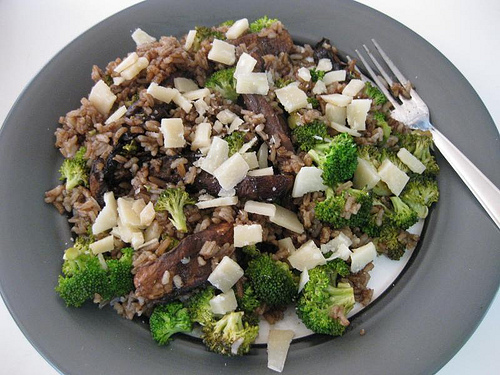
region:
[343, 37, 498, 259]
a large metal fork.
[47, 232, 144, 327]
a piece of broccoli on a plate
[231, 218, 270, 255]
a piece of food on a plate.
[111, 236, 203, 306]
a piece of meat on a plate.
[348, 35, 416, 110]
prongs on a metal fork.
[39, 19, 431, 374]
a pile of food on a plate.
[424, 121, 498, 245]
a handle on a fork.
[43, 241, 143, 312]
a dark green piece of broccoli.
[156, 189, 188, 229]
a piece of broccoli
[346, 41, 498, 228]
a metal fork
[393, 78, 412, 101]
food on the fork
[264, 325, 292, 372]
a piece of white onion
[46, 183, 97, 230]
the rice is brown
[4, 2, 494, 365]
a round gray plate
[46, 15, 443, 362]
food on the plate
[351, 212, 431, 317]
black accent on the plate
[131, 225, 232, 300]
the meat is cooked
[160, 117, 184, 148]
a piece of white cheese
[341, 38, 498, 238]
silver fork on side of plate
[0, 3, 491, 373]
round grey plate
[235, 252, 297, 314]
green broccoli crown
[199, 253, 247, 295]
cheese flake on top of broccoli and meat dish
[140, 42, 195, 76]
brown rice on plate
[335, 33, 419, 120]
four prongs on fork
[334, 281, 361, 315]
green broccoli stalk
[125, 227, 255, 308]
brown meat on plate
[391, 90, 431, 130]
light reflecting on fork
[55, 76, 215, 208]
rice on a table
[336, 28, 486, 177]
fork on a plate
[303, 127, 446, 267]
Broccoli on a plate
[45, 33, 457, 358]
dinner on top of a plate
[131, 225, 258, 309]
meat on a plate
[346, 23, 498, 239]
silver fork on the plate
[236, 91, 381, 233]
beef and broccoli on the plate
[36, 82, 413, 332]
some green broccoli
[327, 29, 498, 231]
a silver fork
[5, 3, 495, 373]
a gray plate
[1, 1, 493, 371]
a white table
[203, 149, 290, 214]
a white cheese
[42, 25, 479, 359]
some brown meat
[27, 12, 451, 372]
some brown rice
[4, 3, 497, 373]
food on a plate